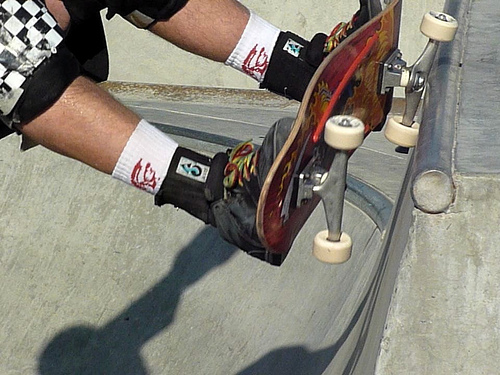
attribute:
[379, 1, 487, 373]
curb — grey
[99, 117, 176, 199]
sock — red, white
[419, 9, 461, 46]
wheel — white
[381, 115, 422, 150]
wheel — under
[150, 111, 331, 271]
shoes — black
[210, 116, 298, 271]
shoe — black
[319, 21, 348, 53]
laces — green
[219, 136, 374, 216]
laces — red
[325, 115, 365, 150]
wheel — White, under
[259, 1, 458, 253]
skateboard — decorated, red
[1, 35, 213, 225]
leg — hairy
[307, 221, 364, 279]
wheel — under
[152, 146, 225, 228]
ankle brace — black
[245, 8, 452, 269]
skateboard — yellow, red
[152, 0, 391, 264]
shoes — black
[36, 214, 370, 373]
shadow — black